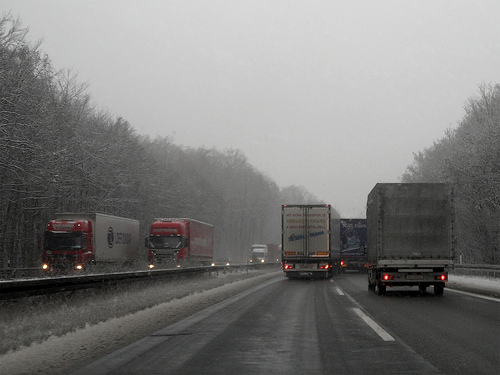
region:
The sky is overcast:
[171, 24, 382, 141]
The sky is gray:
[120, 14, 400, 106]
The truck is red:
[42, 217, 92, 274]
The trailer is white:
[92, 212, 140, 262]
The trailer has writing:
[104, 224, 132, 248]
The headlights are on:
[40, 261, 87, 276]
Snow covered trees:
[5, 29, 277, 211]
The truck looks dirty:
[365, 184, 455, 273]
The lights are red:
[379, 267, 448, 286]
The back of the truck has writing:
[282, 206, 327, 250]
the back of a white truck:
[363, 180, 457, 296]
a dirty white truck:
[364, 180, 460, 302]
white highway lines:
[323, 274, 405, 350]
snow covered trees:
[1, 66, 289, 261]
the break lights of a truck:
[282, 260, 334, 273]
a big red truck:
[143, 216, 218, 266]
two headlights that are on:
[41, 261, 85, 271]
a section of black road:
[86, 290, 498, 374]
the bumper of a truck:
[373, 265, 448, 286]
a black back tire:
[375, 273, 387, 293]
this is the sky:
[151, 15, 358, 85]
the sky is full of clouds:
[211, 13, 418, 125]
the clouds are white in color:
[114, 5, 451, 112]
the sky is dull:
[291, 38, 403, 118]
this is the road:
[238, 300, 368, 374]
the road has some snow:
[248, 301, 326, 360]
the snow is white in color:
[264, 333, 294, 358]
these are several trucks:
[31, 175, 461, 292]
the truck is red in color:
[178, 223, 188, 235]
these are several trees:
[16, 124, 253, 202]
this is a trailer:
[278, 200, 340, 277]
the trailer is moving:
[282, 205, 339, 272]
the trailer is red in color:
[146, 217, 213, 264]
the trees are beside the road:
[28, 130, 140, 193]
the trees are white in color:
[39, 103, 108, 188]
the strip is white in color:
[350, 307, 388, 347]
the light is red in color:
[382, 272, 392, 279]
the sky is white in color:
[236, 38, 394, 120]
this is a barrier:
[103, 269, 141, 311]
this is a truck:
[355, 175, 479, 306]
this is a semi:
[267, 187, 342, 293]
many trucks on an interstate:
[35, 180, 460, 315]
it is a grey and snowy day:
[0, 0, 495, 365]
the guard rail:
[1, 257, 293, 297]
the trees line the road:
[3, 15, 499, 274]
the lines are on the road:
[326, 279, 398, 356]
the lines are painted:
[318, 269, 404, 368]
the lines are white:
[316, 273, 396, 353]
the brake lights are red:
[266, 254, 446, 300]